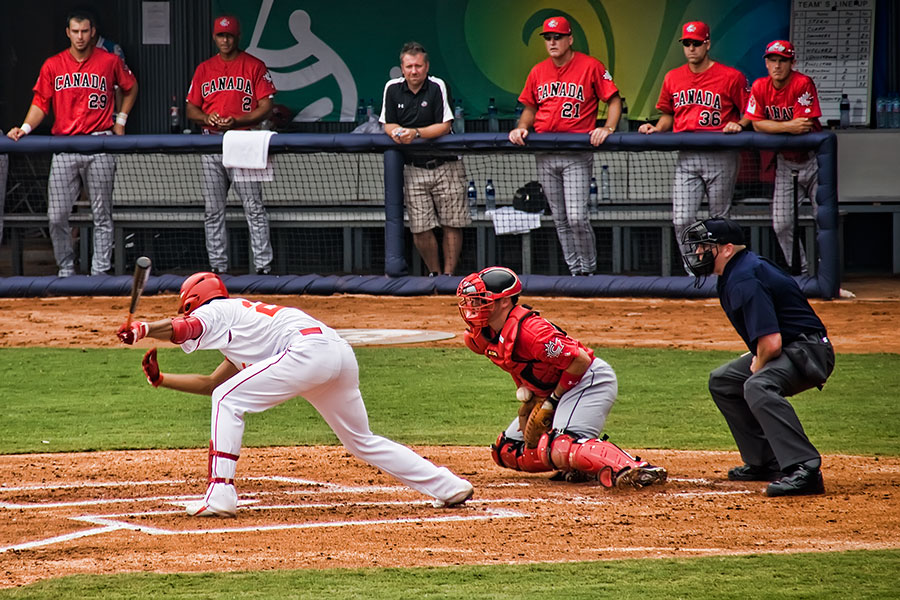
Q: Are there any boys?
A: No, there are no boys.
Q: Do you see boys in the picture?
A: No, there are no boys.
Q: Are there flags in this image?
A: No, there are no flags.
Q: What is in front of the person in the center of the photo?
A: The home plate is in front of the catcher.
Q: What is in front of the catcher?
A: The home plate is in front of the catcher.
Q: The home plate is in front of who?
A: The home plate is in front of the catcher.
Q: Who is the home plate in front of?
A: The home plate is in front of the catcher.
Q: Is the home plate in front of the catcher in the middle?
A: Yes, the home plate is in front of the catcher.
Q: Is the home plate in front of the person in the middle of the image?
A: Yes, the home plate is in front of the catcher.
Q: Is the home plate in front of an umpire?
A: No, the home plate is in front of the catcher.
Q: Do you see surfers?
A: No, there are no surfers.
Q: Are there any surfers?
A: No, there are no surfers.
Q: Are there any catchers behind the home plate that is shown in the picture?
A: Yes, there is a catcher behind the home plate.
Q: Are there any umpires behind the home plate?
A: No, there is a catcher behind the home plate.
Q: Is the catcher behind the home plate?
A: Yes, the catcher is behind the home plate.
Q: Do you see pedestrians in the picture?
A: No, there are no pedestrians.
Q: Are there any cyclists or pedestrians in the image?
A: No, there are no pedestrians or cyclists.